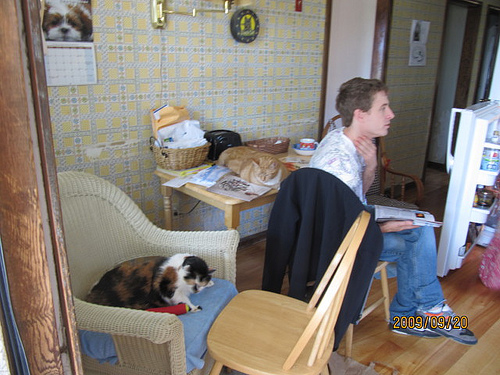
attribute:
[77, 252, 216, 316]
cat — CALICO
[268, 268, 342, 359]
chair — light brown, wooden